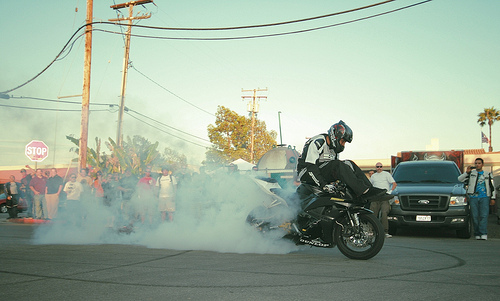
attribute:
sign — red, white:
[25, 135, 57, 158]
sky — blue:
[339, 40, 368, 76]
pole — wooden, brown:
[78, 53, 89, 137]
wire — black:
[212, 25, 242, 54]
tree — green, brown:
[217, 110, 235, 137]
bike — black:
[234, 153, 395, 273]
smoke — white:
[205, 175, 250, 223]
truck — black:
[399, 163, 457, 233]